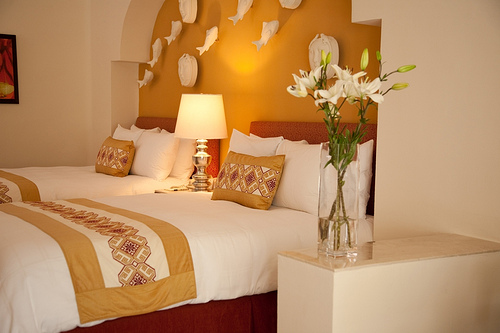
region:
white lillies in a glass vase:
[288, 56, 396, 257]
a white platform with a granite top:
[311, 258, 484, 331]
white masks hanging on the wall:
[167, 54, 354, 87]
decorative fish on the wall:
[169, 2, 286, 47]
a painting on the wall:
[1, 29, 39, 116]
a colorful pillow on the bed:
[211, 146, 271, 204]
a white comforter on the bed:
[194, 211, 251, 265]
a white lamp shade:
[169, 86, 230, 134]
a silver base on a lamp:
[193, 138, 211, 194]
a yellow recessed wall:
[119, 89, 169, 113]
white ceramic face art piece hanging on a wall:
[171, 51, 201, 90]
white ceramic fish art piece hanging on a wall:
[253, 18, 286, 55]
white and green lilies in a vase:
[280, 35, 420, 268]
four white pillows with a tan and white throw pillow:
[95, 110, 202, 188]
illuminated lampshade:
[166, 85, 235, 152]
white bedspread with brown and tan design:
[0, 187, 370, 322]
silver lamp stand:
[189, 135, 216, 192]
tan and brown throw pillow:
[213, 147, 288, 219]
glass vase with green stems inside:
[312, 133, 370, 265]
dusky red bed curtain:
[155, 288, 284, 331]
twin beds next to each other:
[3, 112, 379, 331]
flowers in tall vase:
[291, 48, 420, 268]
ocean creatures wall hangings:
[144, 2, 338, 96]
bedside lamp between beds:
[171, 90, 227, 192]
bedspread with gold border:
[7, 193, 197, 331]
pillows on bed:
[220, 128, 373, 223]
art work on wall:
[2, 32, 28, 107]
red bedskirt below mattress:
[70, 288, 285, 330]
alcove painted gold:
[131, 2, 378, 244]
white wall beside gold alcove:
[351, 3, 498, 255]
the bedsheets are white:
[36, 156, 261, 319]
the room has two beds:
[8, 83, 365, 325]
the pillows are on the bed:
[93, 122, 393, 259]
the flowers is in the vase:
[297, 41, 408, 286]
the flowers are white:
[277, 62, 378, 108]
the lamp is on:
[142, 80, 257, 148]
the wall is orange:
[223, 48, 253, 119]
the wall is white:
[429, 76, 481, 239]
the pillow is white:
[282, 143, 330, 213]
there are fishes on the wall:
[243, 14, 345, 85]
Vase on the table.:
[276, 48, 408, 298]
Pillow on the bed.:
[160, 122, 350, 234]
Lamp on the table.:
[159, 58, 242, 216]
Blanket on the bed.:
[15, 188, 210, 321]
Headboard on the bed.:
[231, 102, 385, 230]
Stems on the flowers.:
[310, 92, 400, 190]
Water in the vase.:
[292, 162, 387, 295]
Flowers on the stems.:
[281, 59, 404, 125]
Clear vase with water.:
[304, 124, 386, 291]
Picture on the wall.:
[0, 6, 51, 113]